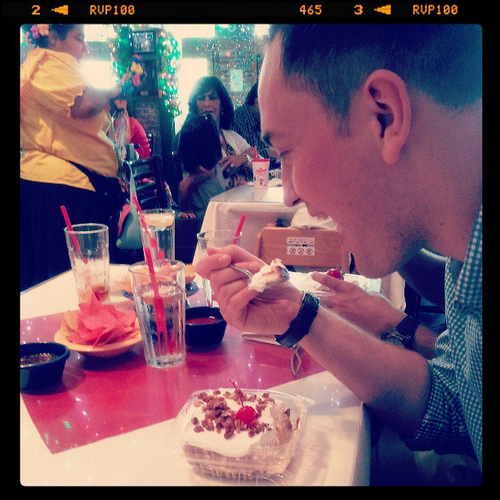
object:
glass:
[127, 255, 189, 371]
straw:
[141, 245, 177, 354]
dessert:
[177, 387, 296, 479]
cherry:
[237, 402, 259, 427]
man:
[190, 21, 484, 474]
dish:
[54, 316, 143, 363]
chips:
[65, 290, 141, 345]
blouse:
[15, 47, 119, 192]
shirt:
[412, 203, 487, 476]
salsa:
[186, 311, 224, 324]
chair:
[126, 150, 172, 212]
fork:
[226, 260, 290, 289]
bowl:
[181, 306, 227, 347]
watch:
[272, 293, 320, 348]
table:
[19, 265, 379, 485]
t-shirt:
[204, 126, 271, 190]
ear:
[361, 68, 413, 167]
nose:
[280, 159, 300, 208]